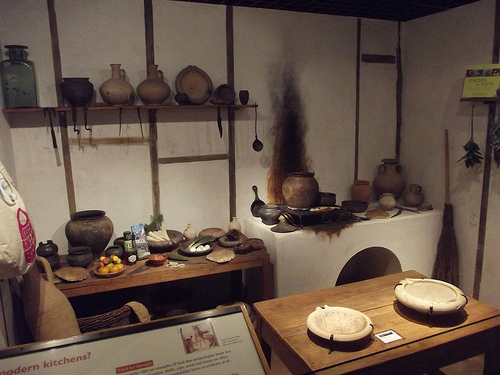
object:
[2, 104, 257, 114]
shelf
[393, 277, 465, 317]
pie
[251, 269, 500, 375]
table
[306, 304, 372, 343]
pie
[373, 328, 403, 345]
sticker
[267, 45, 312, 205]
stain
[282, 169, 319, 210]
pot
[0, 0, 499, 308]
wall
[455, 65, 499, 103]
book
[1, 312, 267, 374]
sign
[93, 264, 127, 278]
plate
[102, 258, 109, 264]
items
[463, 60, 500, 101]
sign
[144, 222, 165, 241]
carrot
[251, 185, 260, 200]
handle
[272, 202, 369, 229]
stove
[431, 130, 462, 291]
sweeper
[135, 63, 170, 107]
jars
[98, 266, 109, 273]
vegetables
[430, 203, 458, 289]
broom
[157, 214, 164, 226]
parsnips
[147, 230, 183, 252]
bowl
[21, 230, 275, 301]
table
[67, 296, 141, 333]
basket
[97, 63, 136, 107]
antiques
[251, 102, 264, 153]
utensils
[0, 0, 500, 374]
display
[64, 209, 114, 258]
antiquity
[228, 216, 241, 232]
antiquity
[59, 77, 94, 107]
antiquity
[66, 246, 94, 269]
antiquity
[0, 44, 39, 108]
antiquity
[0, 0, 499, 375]
museum